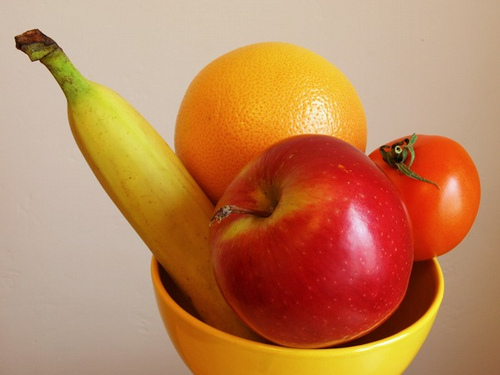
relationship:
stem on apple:
[203, 198, 271, 229] [196, 120, 425, 355]